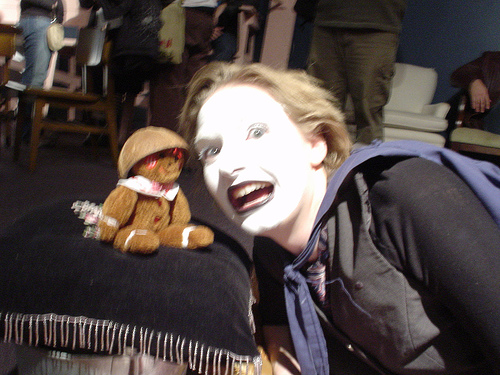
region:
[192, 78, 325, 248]
Woman wearing white face makeup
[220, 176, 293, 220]
Woman has blackened her lips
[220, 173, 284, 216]
Woman's mouth is open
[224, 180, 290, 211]
Woman's teeth look healthy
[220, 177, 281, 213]
Woman's teeth are straight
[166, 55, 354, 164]
Woman has light hair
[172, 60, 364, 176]
Woman has brown hair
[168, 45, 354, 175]
Woman's hair is short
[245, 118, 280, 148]
Woman's eye is wide open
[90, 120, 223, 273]
Teddy bear sitting on pillow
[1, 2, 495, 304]
Halloween party not scary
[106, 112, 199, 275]
brown teddy bear with red eyes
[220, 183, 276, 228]
a white girl with black lipstick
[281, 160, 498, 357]
A girl wearing a vest and cape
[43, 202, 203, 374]
A black pillow on a stool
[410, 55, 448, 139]
A white chair in the backround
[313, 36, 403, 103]
A man with khaki pants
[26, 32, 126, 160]
A wooden chair in the backround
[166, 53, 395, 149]
A women who has blond hair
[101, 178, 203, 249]
A bear who has a cape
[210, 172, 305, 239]
Wearing black lipsticks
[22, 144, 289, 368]
Teddy bear on black pillow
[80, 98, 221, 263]
Teddy bear has a helmet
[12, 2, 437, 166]
People in the background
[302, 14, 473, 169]
A white chair by wall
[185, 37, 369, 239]
This person is a blonde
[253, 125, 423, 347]
This person has a scarf on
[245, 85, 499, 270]
The scarf is blue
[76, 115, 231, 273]
The teddy bear is brown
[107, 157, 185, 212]
Teddy bear is also wearing a scarf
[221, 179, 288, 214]
woman has on black lip stick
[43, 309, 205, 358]
white frigs on the pillow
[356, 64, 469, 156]
chair is a white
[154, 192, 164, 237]
red buttons on the gingerbread man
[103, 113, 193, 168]
gingerbread man is wearing a hat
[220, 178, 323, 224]
woman's mouth is open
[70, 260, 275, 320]
pillow is black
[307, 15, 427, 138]
man is wearing brown pants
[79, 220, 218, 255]
white lines on the gingerbread man's feet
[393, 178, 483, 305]
woman wearing black shirt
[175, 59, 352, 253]
a scary mime in make up.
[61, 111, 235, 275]
a brown teddy bear on a pillow.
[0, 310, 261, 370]
tassels on a black pillow.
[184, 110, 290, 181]
the eyes of a mime.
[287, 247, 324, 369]
a coat string.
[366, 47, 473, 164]
a chair in a room.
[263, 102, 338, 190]
a mime's left ear.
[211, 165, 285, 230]
a mimes mouth.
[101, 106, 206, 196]
a teddy bear's helmet.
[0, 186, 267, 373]
a black pillow with tassels.